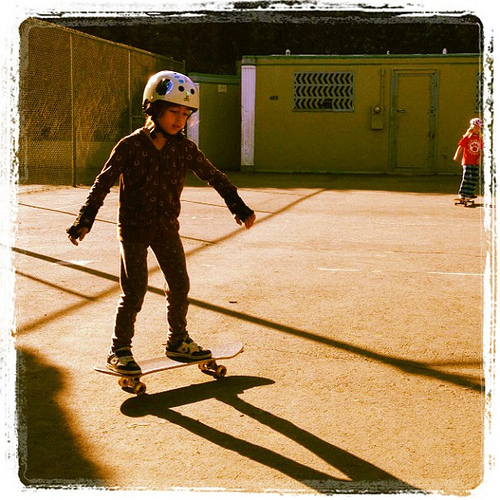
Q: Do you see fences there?
A: Yes, there is a fence.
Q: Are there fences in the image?
A: Yes, there is a fence.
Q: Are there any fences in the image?
A: Yes, there is a fence.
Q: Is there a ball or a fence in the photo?
A: Yes, there is a fence.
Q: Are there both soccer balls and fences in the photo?
A: No, there is a fence but no soccer balls.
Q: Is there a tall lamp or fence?
A: Yes, there is a tall fence.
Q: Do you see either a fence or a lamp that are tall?
A: Yes, the fence is tall.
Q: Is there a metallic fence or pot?
A: Yes, there is a metal fence.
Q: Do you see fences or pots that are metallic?
A: Yes, the fence is metallic.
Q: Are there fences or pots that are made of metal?
A: Yes, the fence is made of metal.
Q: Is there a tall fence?
A: Yes, there is a tall fence.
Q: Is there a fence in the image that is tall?
A: Yes, there is a fence that is tall.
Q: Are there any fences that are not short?
A: Yes, there is a tall fence.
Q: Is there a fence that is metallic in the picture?
A: Yes, there is a metal fence.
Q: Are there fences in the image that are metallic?
A: Yes, there is a fence that is metallic.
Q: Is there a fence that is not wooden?
A: Yes, there is a metallic fence.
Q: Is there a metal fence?
A: Yes, there is a fence that is made of metal.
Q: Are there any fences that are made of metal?
A: Yes, there is a fence that is made of metal.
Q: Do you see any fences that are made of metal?
A: Yes, there is a fence that is made of metal.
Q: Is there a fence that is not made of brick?
A: Yes, there is a fence that is made of metal.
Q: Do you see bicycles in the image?
A: No, there are no bicycles.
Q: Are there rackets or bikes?
A: No, there are no bikes or rackets.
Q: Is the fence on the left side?
A: Yes, the fence is on the left of the image.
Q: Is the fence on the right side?
A: No, the fence is on the left of the image.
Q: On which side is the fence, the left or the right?
A: The fence is on the left of the image.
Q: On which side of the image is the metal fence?
A: The fence is on the left of the image.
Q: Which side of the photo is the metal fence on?
A: The fence is on the left of the image.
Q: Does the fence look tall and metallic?
A: Yes, the fence is tall and metallic.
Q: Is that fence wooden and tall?
A: No, the fence is tall but metallic.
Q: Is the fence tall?
A: Yes, the fence is tall.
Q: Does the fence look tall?
A: Yes, the fence is tall.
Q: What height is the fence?
A: The fence is tall.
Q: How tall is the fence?
A: The fence is tall.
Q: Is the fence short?
A: No, the fence is tall.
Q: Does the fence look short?
A: No, the fence is tall.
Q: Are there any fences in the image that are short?
A: No, there is a fence but it is tall.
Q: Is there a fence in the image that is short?
A: No, there is a fence but it is tall.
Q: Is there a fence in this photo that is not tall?
A: No, there is a fence but it is tall.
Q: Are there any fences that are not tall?
A: No, there is a fence but it is tall.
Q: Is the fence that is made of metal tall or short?
A: The fence is tall.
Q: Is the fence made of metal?
A: Yes, the fence is made of metal.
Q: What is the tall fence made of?
A: The fence is made of metal.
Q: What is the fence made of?
A: The fence is made of metal.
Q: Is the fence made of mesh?
A: No, the fence is made of metal.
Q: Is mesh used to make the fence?
A: No, the fence is made of metal.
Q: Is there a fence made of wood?
A: No, there is a fence but it is made of metal.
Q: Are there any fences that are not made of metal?
A: No, there is a fence but it is made of metal.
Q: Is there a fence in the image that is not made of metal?
A: No, there is a fence but it is made of metal.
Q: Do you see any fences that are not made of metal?
A: No, there is a fence but it is made of metal.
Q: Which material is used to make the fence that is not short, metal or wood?
A: The fence is made of metal.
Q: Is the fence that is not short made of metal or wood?
A: The fence is made of metal.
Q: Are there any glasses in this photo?
A: No, there are no glasses.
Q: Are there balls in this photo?
A: No, there are no balls.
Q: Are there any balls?
A: No, there are no balls.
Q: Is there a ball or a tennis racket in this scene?
A: No, there are no balls or rackets.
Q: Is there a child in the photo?
A: Yes, there is a child.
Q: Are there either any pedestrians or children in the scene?
A: Yes, there is a child.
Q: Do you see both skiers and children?
A: No, there is a child but no skiers.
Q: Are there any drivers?
A: No, there are no drivers.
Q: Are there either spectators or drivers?
A: No, there are no drivers or spectators.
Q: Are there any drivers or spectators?
A: No, there are no drivers or spectators.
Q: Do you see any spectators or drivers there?
A: No, there are no drivers or spectators.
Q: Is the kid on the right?
A: Yes, the kid is on the right of the image.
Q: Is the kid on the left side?
A: No, the kid is on the right of the image.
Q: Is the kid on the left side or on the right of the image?
A: The kid is on the right of the image.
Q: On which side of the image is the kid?
A: The kid is on the right of the image.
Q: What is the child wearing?
A: The kid is wearing a helmet.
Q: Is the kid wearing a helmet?
A: Yes, the kid is wearing a helmet.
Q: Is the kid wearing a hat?
A: No, the kid is wearing a helmet.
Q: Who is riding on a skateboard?
A: The kid is riding on a skateboard.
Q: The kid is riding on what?
A: The kid is riding on a skateboard.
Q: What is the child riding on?
A: The kid is riding on a skateboard.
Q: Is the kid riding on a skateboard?
A: Yes, the kid is riding on a skateboard.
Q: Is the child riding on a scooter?
A: No, the child is riding on a skateboard.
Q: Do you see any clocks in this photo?
A: No, there are no clocks.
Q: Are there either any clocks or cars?
A: No, there are no clocks or cars.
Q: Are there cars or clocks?
A: No, there are no clocks or cars.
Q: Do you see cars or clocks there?
A: No, there are no clocks or cars.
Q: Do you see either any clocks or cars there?
A: No, there are no clocks or cars.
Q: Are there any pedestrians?
A: No, there are no pedestrians.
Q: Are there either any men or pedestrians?
A: No, there are no pedestrians or men.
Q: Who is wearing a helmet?
A: The girl is wearing a helmet.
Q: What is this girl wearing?
A: The girl is wearing a helmet.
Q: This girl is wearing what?
A: The girl is wearing a helmet.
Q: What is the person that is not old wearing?
A: The girl is wearing a helmet.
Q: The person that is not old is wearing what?
A: The girl is wearing a helmet.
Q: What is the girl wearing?
A: The girl is wearing a helmet.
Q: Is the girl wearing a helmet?
A: Yes, the girl is wearing a helmet.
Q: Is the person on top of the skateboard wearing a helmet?
A: Yes, the girl is wearing a helmet.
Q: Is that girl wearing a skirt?
A: No, the girl is wearing a helmet.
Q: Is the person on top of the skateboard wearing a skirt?
A: No, the girl is wearing a helmet.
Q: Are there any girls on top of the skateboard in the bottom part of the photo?
A: Yes, there is a girl on top of the skateboard.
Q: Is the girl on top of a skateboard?
A: Yes, the girl is on top of a skateboard.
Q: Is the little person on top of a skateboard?
A: Yes, the girl is on top of a skateboard.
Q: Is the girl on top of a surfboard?
A: No, the girl is on top of a skateboard.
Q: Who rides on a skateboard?
A: The girl rides on a skateboard.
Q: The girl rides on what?
A: The girl rides on a skateboard.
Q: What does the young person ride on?
A: The girl rides on a skateboard.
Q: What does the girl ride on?
A: The girl rides on a skateboard.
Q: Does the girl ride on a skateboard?
A: Yes, the girl rides on a skateboard.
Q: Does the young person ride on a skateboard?
A: Yes, the girl rides on a skateboard.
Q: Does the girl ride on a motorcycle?
A: No, the girl rides on a skateboard.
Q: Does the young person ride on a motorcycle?
A: No, the girl rides on a skateboard.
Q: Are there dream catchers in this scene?
A: No, there are no dream catchers.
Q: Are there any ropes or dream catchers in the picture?
A: No, there are no dream catchers or ropes.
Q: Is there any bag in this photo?
A: No, there are no bags.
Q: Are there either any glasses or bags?
A: No, there are no bags or glasses.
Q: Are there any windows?
A: Yes, there is a window.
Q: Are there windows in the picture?
A: Yes, there is a window.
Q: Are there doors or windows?
A: Yes, there is a window.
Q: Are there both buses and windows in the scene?
A: No, there is a window but no buses.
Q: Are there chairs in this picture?
A: No, there are no chairs.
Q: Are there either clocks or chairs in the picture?
A: No, there are no chairs or clocks.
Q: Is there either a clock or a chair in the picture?
A: No, there are no chairs or clocks.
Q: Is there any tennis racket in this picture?
A: No, there are no rackets.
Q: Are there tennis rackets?
A: No, there are no tennis rackets.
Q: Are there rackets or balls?
A: No, there are no rackets or balls.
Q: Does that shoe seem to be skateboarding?
A: Yes, the shoe is skateboarding.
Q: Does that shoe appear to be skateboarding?
A: Yes, the shoe is skateboarding.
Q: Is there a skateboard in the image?
A: Yes, there is a skateboard.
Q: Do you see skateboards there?
A: Yes, there is a skateboard.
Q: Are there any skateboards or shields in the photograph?
A: Yes, there is a skateboard.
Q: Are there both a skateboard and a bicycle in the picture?
A: No, there is a skateboard but no bicycles.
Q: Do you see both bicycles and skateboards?
A: No, there is a skateboard but no bicycles.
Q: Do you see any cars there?
A: No, there are no cars.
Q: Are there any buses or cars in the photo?
A: No, there are no cars or buses.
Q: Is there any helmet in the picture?
A: Yes, there is a helmet.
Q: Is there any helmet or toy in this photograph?
A: Yes, there is a helmet.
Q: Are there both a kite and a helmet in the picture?
A: No, there is a helmet but no kites.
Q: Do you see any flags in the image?
A: No, there are no flags.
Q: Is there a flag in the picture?
A: No, there are no flags.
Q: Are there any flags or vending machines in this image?
A: No, there are no flags or vending machines.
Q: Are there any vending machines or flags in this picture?
A: No, there are no flags or vending machines.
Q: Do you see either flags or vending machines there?
A: No, there are no flags or vending machines.